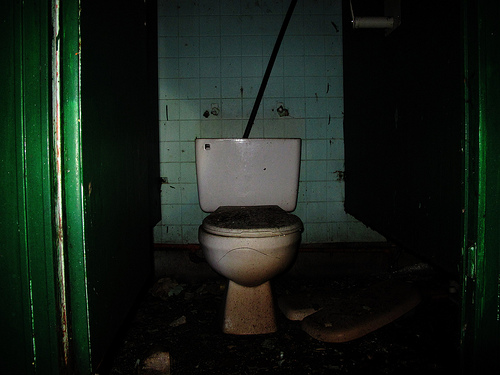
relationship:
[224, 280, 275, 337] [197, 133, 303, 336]
stand on toilet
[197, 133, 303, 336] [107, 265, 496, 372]
toilet on floor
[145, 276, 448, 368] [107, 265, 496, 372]
dirt on trash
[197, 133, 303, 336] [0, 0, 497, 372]
toilet in bathroom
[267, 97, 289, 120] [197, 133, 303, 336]
tile behind toilet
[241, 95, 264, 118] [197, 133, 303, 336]
tile behind toilet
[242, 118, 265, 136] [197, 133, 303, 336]
tile behind toilet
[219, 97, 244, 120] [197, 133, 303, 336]
tile behind toilet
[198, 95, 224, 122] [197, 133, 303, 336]
tile behind toilet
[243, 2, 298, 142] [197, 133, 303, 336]
pole behind toilet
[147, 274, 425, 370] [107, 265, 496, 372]
trash on floor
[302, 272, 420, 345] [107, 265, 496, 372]
lid on floor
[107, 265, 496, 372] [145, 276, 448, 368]
floor covered in dirt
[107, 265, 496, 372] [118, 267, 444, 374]
floor covered in garbage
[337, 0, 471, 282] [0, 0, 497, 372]
door in bathroom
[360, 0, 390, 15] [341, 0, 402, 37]
hole in handle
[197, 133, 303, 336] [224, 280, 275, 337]
toilet has base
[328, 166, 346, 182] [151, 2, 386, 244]
marks on wall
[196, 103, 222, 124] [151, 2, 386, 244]
marks on wall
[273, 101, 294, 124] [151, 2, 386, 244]
marks on wall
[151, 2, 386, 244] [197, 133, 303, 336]
wall behind toilet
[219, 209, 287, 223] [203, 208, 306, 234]
something in seat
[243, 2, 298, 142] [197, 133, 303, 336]
pole in toilet